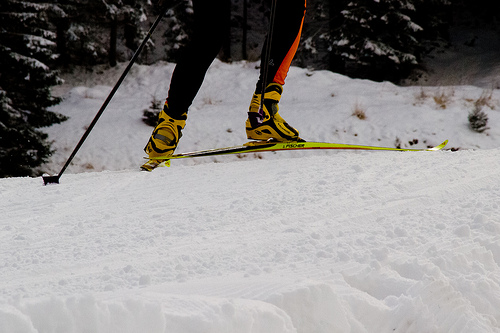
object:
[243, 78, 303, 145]
shoe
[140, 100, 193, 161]
shoe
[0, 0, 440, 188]
pine tree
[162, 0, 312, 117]
pants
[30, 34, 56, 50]
snow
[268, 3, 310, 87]
stripe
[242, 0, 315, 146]
leg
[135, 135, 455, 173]
ski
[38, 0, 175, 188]
pole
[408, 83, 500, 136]
dead grass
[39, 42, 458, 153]
hill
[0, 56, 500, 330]
snow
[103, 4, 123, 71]
tree trunk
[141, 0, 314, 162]
man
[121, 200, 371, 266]
ground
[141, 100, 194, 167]
foot